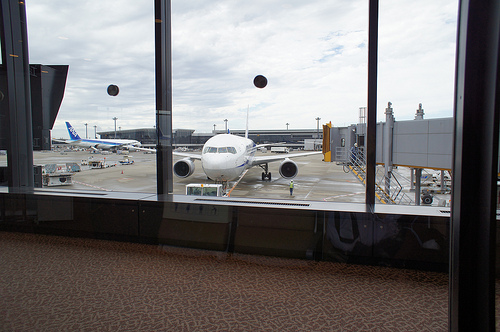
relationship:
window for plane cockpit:
[225, 146, 237, 153] [196, 138, 255, 185]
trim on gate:
[322, 123, 332, 163] [324, 103, 451, 202]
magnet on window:
[254, 75, 267, 89] [166, 2, 367, 208]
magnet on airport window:
[108, 85, 119, 95] [25, 0, 156, 200]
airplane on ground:
[126, 104, 322, 196] [32, 141, 447, 204]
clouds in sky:
[17, 1, 463, 137] [23, 4, 455, 145]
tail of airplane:
[56, 117, 89, 156] [49, 128, 139, 154]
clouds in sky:
[17, 1, 463, 137] [59, 6, 398, 138]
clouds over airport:
[17, 1, 463, 137] [14, 22, 407, 293]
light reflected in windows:
[4, 48, 24, 66] [1, 0, 460, 215]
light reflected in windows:
[0, 63, 70, 149] [1, 0, 460, 215]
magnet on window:
[106, 84, 119, 96] [2, 0, 497, 221]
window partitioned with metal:
[375, 2, 456, 216] [135, 8, 182, 189]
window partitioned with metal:
[166, 2, 367, 208] [135, 8, 182, 189]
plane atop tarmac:
[121, 100, 324, 189] [0, 142, 452, 207]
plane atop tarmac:
[50, 120, 142, 154] [0, 142, 452, 207]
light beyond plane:
[107, 112, 124, 126] [106, 106, 338, 213]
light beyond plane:
[81, 116, 91, 129] [106, 106, 338, 213]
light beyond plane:
[88, 119, 107, 141] [106, 106, 338, 213]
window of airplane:
[225, 144, 237, 153] [126, 112, 327, 192]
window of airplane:
[217, 146, 225, 153] [126, 112, 327, 192]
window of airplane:
[204, 147, 216, 152] [126, 112, 327, 192]